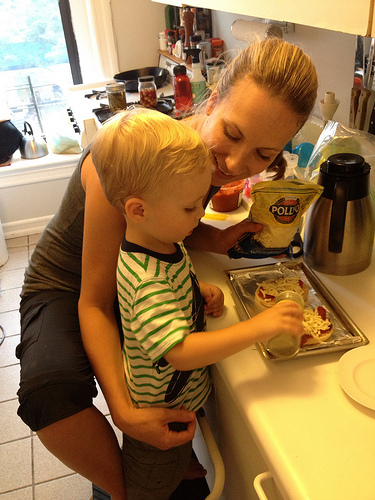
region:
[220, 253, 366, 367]
mini pizzas in a tray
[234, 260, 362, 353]
two small pizzas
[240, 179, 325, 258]
a bag of mozzerella cheese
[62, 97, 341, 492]
a boy making pizzas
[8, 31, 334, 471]
a mom helping her son cook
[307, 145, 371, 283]
a black and silver coffee pot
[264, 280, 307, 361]
a bottle of oil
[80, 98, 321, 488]
a boy in a striped shirt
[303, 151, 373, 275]
a large coffe crafe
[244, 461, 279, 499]
the handle on a cabinet drawer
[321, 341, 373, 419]
a white plate on a counter top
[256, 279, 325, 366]
a boy helping make food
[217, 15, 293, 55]
a paper towel rack on the wall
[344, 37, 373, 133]
kitchen knives near a counter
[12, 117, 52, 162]
a metal tea kettle by a window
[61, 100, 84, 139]
black control knobs on a white stove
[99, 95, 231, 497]
this is a little boy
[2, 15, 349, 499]
this is a woman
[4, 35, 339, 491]
woman holding little boy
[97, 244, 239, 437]
little boy wearing a striped shirt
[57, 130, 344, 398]
boy making a pizza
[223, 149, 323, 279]
woman holding a bag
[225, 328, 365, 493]
a white kitchen counter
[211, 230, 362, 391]
a silver baking sheet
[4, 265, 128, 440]
woman wearing black shorts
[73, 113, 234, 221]
little boy has blonde hair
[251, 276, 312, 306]
an uncooked pizza with cheese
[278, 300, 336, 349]
an uncooked pizza with cheese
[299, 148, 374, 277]
a coffee pot on a table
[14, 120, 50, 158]
a coffee pot on a counter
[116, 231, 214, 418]
a boy with a green striped shirt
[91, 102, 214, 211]
a boy with blond hair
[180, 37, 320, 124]
a woman with blonde hair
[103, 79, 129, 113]
a jar of food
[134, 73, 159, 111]
a jar of food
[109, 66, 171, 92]
a black pan on a stove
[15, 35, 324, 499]
Mother and son making small pizzas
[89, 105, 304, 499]
Boy pouring cheese on pizzas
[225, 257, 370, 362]
Two small uncooked pizzas on a pan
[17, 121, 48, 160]
Silver teapot with a black handle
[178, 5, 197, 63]
Brown wood pepper grinder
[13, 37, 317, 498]
Mother and son baking in a kitchen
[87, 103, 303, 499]
Boy wearing a white shirt with green stripes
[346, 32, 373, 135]
Two knives with wood handles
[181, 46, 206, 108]
Plastic spray bottle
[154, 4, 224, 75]
Spices on a wood shelf